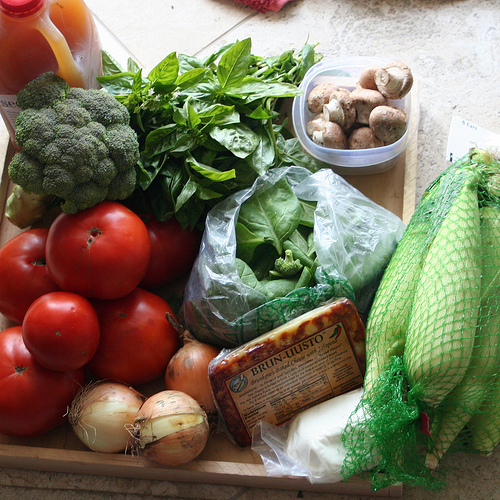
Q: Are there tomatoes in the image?
A: Yes, there is a tomato.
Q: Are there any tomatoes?
A: Yes, there is a tomato.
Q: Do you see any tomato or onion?
A: Yes, there is a tomato.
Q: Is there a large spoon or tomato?
A: Yes, there is a large tomato.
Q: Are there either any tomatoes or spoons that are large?
A: Yes, the tomato is large.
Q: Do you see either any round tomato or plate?
A: Yes, there is a round tomato.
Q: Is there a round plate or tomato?
A: Yes, there is a round tomato.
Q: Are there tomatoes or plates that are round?
A: Yes, the tomato is round.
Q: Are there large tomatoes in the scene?
A: Yes, there is a large tomato.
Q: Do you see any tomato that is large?
A: Yes, there is a tomato that is large.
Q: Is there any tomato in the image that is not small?
A: Yes, there is a large tomato.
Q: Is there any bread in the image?
A: No, there is no breads.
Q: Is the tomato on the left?
A: Yes, the tomato is on the left of the image.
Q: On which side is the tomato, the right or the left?
A: The tomato is on the left of the image.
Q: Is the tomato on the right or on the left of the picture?
A: The tomato is on the left of the image.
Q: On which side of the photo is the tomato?
A: The tomato is on the left of the image.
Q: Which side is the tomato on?
A: The tomato is on the left of the image.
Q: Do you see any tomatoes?
A: Yes, there is a tomato.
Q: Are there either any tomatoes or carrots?
A: Yes, there is a tomato.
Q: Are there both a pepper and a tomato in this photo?
A: No, there is a tomato but no peppers.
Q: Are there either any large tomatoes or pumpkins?
A: Yes, there is a large tomato.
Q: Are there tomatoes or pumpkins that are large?
A: Yes, the tomato is large.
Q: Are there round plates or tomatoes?
A: Yes, there is a round tomato.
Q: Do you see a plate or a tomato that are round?
A: Yes, the tomato is round.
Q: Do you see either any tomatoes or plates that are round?
A: Yes, the tomato is round.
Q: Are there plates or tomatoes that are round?
A: Yes, the tomato is round.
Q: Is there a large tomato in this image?
A: Yes, there is a large tomato.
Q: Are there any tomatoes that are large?
A: Yes, there is a tomato that is large.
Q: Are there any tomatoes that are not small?
A: Yes, there is a large tomato.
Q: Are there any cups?
A: No, there are no cups.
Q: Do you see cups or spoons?
A: No, there are no cups or spoons.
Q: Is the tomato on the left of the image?
A: Yes, the tomato is on the left of the image.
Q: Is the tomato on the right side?
A: No, the tomato is on the left of the image.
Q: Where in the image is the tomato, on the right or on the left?
A: The tomato is on the left of the image.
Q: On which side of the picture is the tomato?
A: The tomato is on the left of the image.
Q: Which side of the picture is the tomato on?
A: The tomato is on the left of the image.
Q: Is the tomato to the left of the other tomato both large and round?
A: Yes, the tomato is large and round.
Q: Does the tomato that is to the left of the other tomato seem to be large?
A: Yes, the tomato is large.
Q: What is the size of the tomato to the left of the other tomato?
A: The tomato is large.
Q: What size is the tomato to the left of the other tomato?
A: The tomato is large.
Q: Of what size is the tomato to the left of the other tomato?
A: The tomato is large.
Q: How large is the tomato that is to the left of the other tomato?
A: The tomato is large.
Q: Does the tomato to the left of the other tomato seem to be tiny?
A: No, the tomato is large.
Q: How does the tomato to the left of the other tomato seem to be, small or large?
A: The tomato is large.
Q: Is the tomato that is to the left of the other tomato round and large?
A: Yes, the tomato is round and large.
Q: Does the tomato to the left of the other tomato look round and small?
A: No, the tomato is round but large.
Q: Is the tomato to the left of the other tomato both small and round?
A: No, the tomato is round but large.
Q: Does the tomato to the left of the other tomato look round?
A: Yes, the tomato is round.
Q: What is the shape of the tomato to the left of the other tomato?
A: The tomato is round.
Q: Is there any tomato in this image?
A: Yes, there is a tomato.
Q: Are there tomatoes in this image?
A: Yes, there is a tomato.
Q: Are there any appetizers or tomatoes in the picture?
A: Yes, there is a tomato.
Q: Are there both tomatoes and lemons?
A: No, there is a tomato but no lemons.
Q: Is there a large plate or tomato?
A: Yes, there is a large tomato.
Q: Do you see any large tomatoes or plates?
A: Yes, there is a large tomato.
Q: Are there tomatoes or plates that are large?
A: Yes, the tomato is large.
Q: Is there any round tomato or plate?
A: Yes, there is a round tomato.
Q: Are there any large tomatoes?
A: Yes, there is a large tomato.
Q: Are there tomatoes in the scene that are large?
A: Yes, there is a tomato that is large.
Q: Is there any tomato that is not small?
A: Yes, there is a large tomato.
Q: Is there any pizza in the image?
A: No, there are no pizzas.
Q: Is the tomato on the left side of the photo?
A: Yes, the tomato is on the left of the image.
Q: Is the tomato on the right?
A: No, the tomato is on the left of the image.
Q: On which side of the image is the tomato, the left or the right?
A: The tomato is on the left of the image.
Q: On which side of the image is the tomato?
A: The tomato is on the left of the image.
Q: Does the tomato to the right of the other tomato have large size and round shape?
A: Yes, the tomato is large and round.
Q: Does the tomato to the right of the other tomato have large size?
A: Yes, the tomato is large.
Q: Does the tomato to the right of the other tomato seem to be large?
A: Yes, the tomato is large.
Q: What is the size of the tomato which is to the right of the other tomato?
A: The tomato is large.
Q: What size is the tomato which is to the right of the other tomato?
A: The tomato is large.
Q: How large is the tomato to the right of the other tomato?
A: The tomato is large.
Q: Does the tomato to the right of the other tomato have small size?
A: No, the tomato is large.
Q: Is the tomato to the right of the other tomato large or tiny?
A: The tomato is large.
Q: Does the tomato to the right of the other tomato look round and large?
A: Yes, the tomato is round and large.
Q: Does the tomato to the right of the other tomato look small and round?
A: No, the tomato is round but large.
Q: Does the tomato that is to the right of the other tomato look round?
A: Yes, the tomato is round.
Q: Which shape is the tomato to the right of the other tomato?
A: The tomato is round.